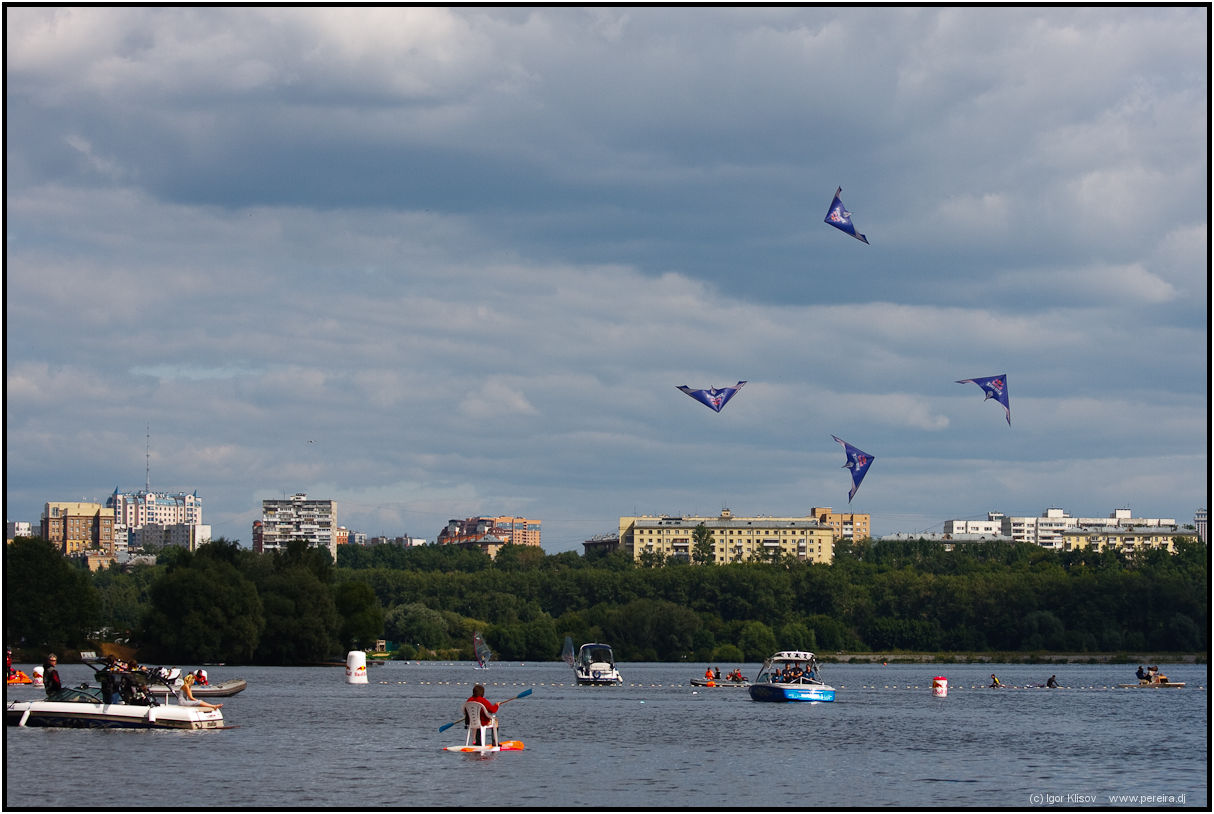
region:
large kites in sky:
[679, 155, 1084, 508]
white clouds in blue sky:
[76, 148, 211, 265]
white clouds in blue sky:
[267, 373, 357, 414]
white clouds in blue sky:
[496, 279, 568, 320]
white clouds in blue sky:
[322, 300, 478, 400]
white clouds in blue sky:
[548, 103, 672, 220]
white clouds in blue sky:
[1127, 54, 1210, 164]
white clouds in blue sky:
[1009, 0, 1130, 169]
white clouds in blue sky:
[364, 141, 478, 203]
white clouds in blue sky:
[124, 311, 311, 425]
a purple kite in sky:
[668, 379, 742, 413]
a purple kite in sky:
[829, 431, 882, 505]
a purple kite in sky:
[963, 374, 1015, 420]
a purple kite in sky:
[824, 183, 869, 245]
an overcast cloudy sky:
[4, 8, 1209, 559]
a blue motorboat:
[751, 650, 834, 702]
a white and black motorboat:
[573, 644, 618, 685]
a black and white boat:
[18, 653, 231, 732]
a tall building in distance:
[259, 495, 340, 559]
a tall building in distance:
[436, 516, 538, 559]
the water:
[591, 723, 741, 804]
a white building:
[121, 487, 200, 551]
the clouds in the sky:
[340, 254, 546, 453]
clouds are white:
[385, 362, 542, 479]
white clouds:
[401, 350, 546, 441]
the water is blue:
[888, 730, 1007, 775]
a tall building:
[262, 496, 343, 542]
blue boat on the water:
[749, 638, 835, 705]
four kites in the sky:
[616, 177, 1077, 515]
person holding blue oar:
[427, 688, 534, 745]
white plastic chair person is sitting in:
[465, 699, 496, 744]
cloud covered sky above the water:
[19, 14, 1194, 534]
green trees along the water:
[12, 527, 1201, 665]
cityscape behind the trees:
[19, 489, 1210, 565]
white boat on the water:
[12, 697, 230, 729]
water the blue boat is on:
[21, 666, 1210, 809]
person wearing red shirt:
[467, 683, 494, 741]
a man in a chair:
[441, 673, 539, 756]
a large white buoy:
[344, 652, 371, 686]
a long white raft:
[13, 695, 222, 738]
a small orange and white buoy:
[927, 676, 951, 702]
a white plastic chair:
[455, 697, 500, 743]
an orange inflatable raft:
[455, 730, 527, 764]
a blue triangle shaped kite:
[952, 362, 1012, 415]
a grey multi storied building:
[256, 491, 337, 556]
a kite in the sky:
[672, 375, 755, 409]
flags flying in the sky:
[673, 160, 1025, 510]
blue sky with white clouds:
[28, 21, 1212, 539]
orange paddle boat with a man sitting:
[436, 668, 540, 758]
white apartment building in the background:
[252, 484, 356, 575]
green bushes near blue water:
[6, 508, 1202, 662]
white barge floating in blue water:
[14, 675, 223, 744]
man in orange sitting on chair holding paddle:
[446, 671, 548, 742]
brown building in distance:
[425, 505, 544, 555]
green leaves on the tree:
[515, 571, 541, 597]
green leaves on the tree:
[623, 565, 640, 587]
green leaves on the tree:
[663, 596, 695, 634]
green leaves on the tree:
[723, 591, 773, 643]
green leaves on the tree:
[774, 566, 803, 602]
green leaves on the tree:
[801, 575, 854, 611]